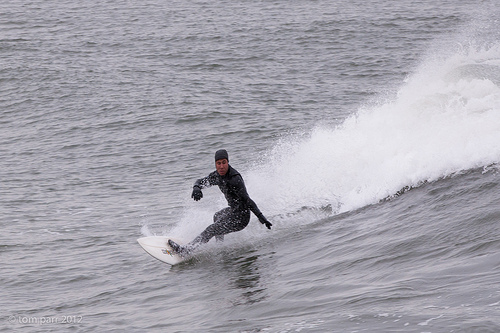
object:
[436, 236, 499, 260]
wave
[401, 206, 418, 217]
sky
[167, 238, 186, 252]
foot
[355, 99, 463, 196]
waves ocean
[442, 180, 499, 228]
wave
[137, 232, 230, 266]
board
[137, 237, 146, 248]
tip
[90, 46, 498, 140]
ocean waves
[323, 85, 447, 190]
waves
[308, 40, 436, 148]
gray ocean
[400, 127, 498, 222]
ocean wavey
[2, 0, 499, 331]
ocean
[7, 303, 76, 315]
wave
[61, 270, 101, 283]
wave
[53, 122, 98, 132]
wave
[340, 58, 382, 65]
wave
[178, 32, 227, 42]
wave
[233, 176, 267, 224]
arm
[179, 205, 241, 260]
leg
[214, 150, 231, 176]
head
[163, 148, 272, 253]
man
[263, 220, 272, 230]
left hand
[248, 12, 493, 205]
water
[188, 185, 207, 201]
right hand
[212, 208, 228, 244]
leg